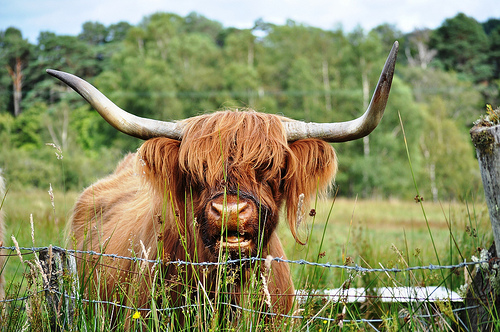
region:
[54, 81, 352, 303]
a steer standing in a field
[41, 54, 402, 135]
black and white horns of the steer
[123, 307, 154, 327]
yellow flower of a plant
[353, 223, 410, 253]
green grass of the field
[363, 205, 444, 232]
brown patch of dirt in the field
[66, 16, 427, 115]
trees growing behind the field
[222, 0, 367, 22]
cloudy white skies over the field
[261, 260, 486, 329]
grey barbed wire of the fence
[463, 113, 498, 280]
grey wood post of the fence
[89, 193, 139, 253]
brown fur of the steer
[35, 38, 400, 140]
Large horns on a cow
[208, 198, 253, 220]
Nose on a brown cow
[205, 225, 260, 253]
Mouth open on a brown cow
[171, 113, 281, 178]
Hair covering the eyes of a cow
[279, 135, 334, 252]
Cow's hairy ear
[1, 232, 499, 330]
Fence in front of a cow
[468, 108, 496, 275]
Wooden fence post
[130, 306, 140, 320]
Yellow flower growing in front of a cow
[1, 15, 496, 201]
Trees behind a brown cow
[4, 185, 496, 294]
Brown cow standing in a grass field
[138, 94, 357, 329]
an ox has two horn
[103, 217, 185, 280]
a barb wire fence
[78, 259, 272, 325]
overgrown grass is behind the fence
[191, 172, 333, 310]
the ox has a muzzle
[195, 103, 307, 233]
the ox has overgrown hair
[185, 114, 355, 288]
the ox has brown hair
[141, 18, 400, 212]
the grass is in the background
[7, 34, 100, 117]
the trees are behind the ox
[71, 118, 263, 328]
the ox has brown fur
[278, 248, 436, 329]
a table is behind the ox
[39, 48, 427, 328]
this is a cow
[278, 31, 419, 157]
the horn of a cow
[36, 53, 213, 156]
the horn of a cow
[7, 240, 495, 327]
this is a barbed wire fence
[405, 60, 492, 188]
this is a tree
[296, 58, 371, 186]
this is a tree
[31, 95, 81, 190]
this is a tree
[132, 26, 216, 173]
this is a tree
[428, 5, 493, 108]
this is a tree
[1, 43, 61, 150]
this is a tree